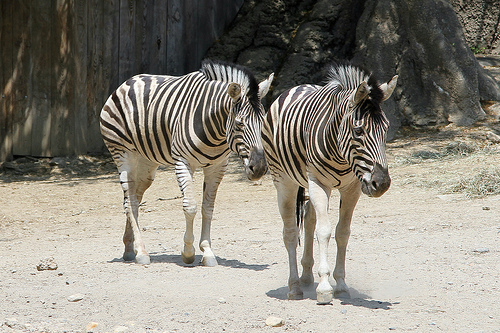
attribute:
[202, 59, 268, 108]
mane — striped, white, black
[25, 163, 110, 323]
ground — rocky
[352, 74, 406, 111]
ears — zebra's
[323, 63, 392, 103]
mane — stiff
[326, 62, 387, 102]
mane — stiff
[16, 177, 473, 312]
ground — dirt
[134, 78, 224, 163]
stripes — white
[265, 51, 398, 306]
zebra — walking, hairly, black, stripped, white, colour, colored, standing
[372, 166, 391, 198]
nose — black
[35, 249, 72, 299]
rocks — beige, small, few, black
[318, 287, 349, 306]
hooves — white, zebra's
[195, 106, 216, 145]
stripes — black, white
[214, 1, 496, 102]
trunk — brown, huge, large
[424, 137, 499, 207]
grass — brown, dead, dry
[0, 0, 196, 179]
fence — wooden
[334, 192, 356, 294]
leg — white